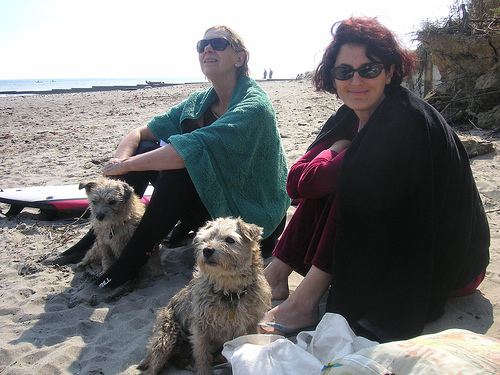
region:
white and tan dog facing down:
[69, 169, 158, 273]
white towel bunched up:
[240, 308, 369, 369]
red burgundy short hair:
[312, 4, 390, 76]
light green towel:
[157, 79, 282, 205]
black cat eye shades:
[327, 62, 393, 81]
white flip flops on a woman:
[250, 319, 313, 336]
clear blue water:
[0, 70, 153, 87]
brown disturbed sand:
[21, 104, 128, 172]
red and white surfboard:
[20, 173, 96, 238]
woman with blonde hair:
[174, 28, 305, 123]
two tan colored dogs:
[73, 177, 273, 372]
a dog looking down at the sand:
[78, 177, 166, 292]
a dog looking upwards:
[133, 214, 273, 374]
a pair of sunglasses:
[196, 35, 231, 52]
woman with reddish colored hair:
[252, 13, 497, 345]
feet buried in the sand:
[30, 252, 135, 308]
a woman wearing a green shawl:
[63, 25, 288, 302]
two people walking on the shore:
[261, 64, 275, 80]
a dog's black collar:
[208, 283, 256, 298]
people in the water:
[35, 79, 58, 86]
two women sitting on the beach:
[41, 11, 490, 343]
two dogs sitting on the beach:
[75, 177, 272, 372]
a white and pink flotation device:
[0, 185, 153, 220]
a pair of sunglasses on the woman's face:
[331, 62, 387, 80]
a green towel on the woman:
[146, 74, 289, 243]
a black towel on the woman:
[306, 80, 491, 344]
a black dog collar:
[213, 277, 253, 302]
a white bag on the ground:
[222, 311, 380, 373]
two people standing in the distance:
[263, 67, 275, 77]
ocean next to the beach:
[0, 78, 187, 96]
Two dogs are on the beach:
[77, 7, 452, 321]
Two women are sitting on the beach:
[77, 14, 450, 345]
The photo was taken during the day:
[51, 14, 466, 349]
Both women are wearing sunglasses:
[54, 4, 461, 282]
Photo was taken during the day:
[40, 11, 468, 366]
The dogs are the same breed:
[51, 83, 334, 372]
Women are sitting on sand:
[92, 16, 462, 373]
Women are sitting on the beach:
[39, 23, 471, 364]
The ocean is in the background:
[18, 13, 405, 285]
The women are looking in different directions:
[28, 24, 484, 309]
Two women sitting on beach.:
[46, 4, 484, 351]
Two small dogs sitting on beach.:
[48, 180, 293, 371]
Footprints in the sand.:
[12, 98, 85, 168]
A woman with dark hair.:
[305, 10, 481, 340]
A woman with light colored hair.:
[133, 1, 288, 230]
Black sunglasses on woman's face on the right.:
[302, 0, 420, 125]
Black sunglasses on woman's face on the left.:
[160, 5, 260, 98]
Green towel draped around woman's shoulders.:
[136, 74, 292, 226]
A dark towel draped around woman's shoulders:
[306, 100, 486, 327]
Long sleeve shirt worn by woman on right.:
[281, 10, 483, 332]